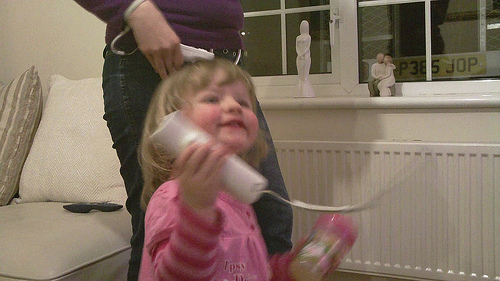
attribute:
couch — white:
[0, 72, 160, 279]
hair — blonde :
[135, 53, 275, 215]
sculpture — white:
[277, 17, 326, 107]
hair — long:
[154, 62, 248, 82]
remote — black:
[63, 196, 125, 218]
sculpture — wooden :
[342, 44, 423, 97]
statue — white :
[282, 10, 340, 123]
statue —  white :
[289, 22, 336, 111]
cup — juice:
[291, 201, 358, 279]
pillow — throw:
[18, 72, 128, 211]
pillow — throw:
[3, 63, 43, 204]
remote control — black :
[63, 200, 123, 212]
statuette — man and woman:
[363, 52, 401, 98]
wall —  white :
[33, 17, 82, 52]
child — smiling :
[133, 55, 348, 279]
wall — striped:
[353, 107, 431, 129]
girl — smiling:
[144, 59, 331, 279]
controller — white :
[104, 89, 353, 266]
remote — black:
[68, 194, 115, 212]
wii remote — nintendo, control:
[139, 116, 291, 218]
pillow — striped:
[0, 65, 45, 210]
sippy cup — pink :
[279, 209, 364, 277]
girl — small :
[136, 58, 343, 279]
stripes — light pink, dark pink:
[156, 198, 226, 279]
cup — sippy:
[284, 209, 364, 279]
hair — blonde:
[149, 80, 177, 117]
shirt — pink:
[134, 176, 270, 279]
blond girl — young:
[141, 58, 264, 186]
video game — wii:
[152, 110, 294, 202]